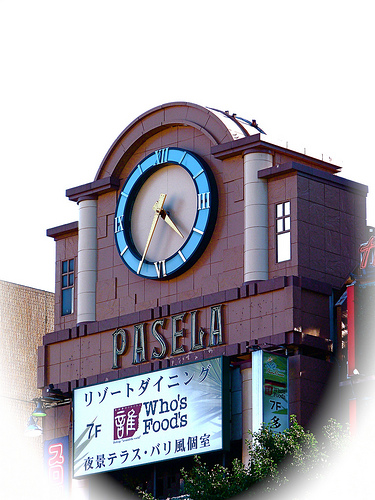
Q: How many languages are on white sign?
A: Two.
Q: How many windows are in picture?
A: Two.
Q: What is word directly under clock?
A: Pasela.